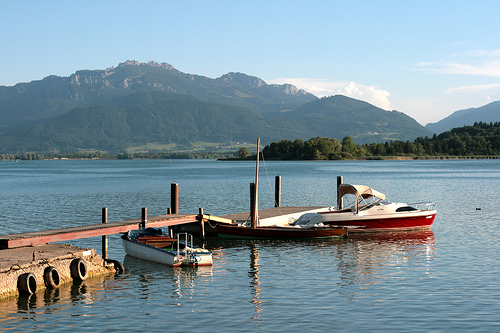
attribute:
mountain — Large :
[3, 52, 498, 147]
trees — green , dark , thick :
[249, 120, 499, 159]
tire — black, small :
[20, 272, 38, 297]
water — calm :
[3, 157, 496, 326]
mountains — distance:
[2, 57, 489, 167]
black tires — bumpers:
[11, 254, 98, 301]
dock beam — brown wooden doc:
[269, 172, 286, 206]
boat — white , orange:
[289, 176, 437, 241]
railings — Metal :
[345, 193, 376, 210]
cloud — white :
[270, 70, 497, 123]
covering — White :
[338, 184, 383, 201]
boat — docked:
[120, 220, 210, 273]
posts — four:
[158, 168, 302, 235]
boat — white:
[112, 214, 221, 279]